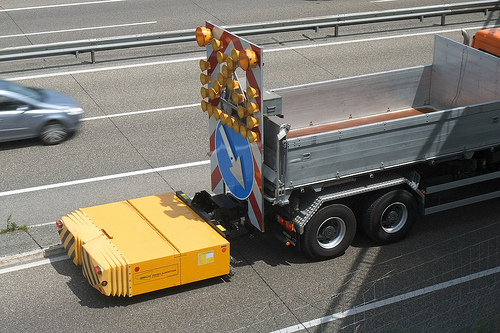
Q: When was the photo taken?
A: Daytime.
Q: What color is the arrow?
A: White.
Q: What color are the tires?
A: Black.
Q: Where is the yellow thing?
A: On the street.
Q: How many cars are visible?
A: Two.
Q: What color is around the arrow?
A: Blue.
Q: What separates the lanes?
A: White lines.